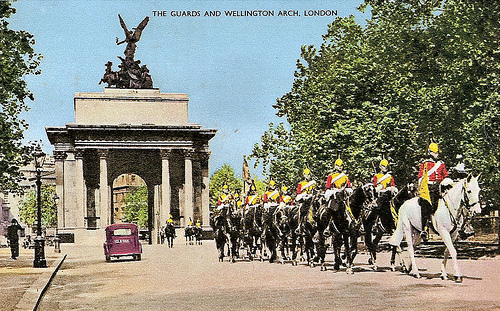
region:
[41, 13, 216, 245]
Vintage view of Wellington Arch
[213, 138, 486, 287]
Line of traditionally dressed guards on horseback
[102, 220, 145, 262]
Rear view of vintage automobile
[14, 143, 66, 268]
Vintage street lamp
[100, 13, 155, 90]
Winged angellic statue monument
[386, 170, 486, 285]
White horse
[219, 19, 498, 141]
Green-leafed tree foliage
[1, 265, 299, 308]
Dirt sidewalk along dirt street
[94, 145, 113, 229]
Stone, architectural column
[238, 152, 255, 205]
Military parade flag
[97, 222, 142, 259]
Red vehicle on the road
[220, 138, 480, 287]
Group of men riding horses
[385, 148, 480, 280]
White horse leading the pack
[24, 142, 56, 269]
Black lamp post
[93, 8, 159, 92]
Statue on the top of stone structure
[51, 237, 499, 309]
Stone road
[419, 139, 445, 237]
Man riding white horse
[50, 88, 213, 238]
Stone structure with under pass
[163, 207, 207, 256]
Group of horses in the background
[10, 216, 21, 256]
Man walking down the sidewalk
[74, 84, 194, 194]
this is a building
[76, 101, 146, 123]
this is a wall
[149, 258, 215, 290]
this is the ground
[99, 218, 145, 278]
this is a car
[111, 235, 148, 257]
the car is red in color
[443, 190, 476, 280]
this is a horse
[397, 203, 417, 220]
the horse is white in color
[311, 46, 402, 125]
this is a tree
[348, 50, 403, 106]
the leaves are green in color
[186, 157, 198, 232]
this is a pillar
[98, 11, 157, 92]
Statue on top of doorway.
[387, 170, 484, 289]
White horse in front.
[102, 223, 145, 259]
Red car on the road.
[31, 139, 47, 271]
Light pole on side of road.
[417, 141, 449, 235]
Red and black uniform on man.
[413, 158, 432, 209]
Yellow flag in his hand.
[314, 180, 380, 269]
Black horse in the line.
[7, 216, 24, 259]
Man walking on the street.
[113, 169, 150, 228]
Building in the background.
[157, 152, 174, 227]
Stone column on front of structure.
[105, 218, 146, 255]
this is a car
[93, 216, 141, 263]
the car is moving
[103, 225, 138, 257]
the car is red in color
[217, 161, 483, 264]
these are horses moving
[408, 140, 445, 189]
the soldier is on the horse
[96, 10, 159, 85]
a stature is on top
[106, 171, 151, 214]
the door is open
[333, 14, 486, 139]
the trees are leafy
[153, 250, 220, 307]
this is a road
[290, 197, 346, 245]
the horses are black in color